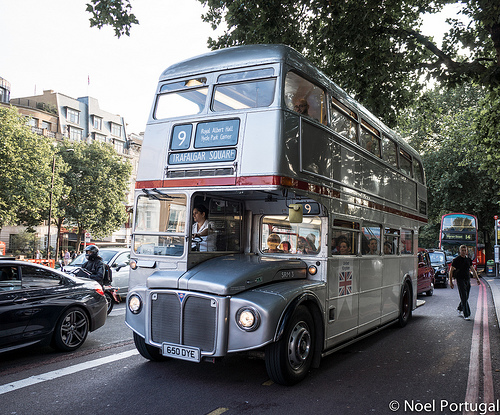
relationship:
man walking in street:
[447, 244, 481, 321] [408, 330, 468, 395]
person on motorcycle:
[75, 245, 105, 287] [58, 226, 116, 281]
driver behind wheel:
[192, 205, 217, 252] [183, 233, 200, 242]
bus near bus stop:
[436, 213, 478, 273] [476, 248, 486, 266]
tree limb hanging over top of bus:
[199, 2, 499, 85] [120, 37, 432, 388]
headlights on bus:
[127, 294, 257, 332] [135, 50, 465, 390]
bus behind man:
[439, 213, 495, 272] [447, 244, 481, 321]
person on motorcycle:
[73, 244, 115, 288] [56, 263, 118, 318]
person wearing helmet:
[73, 244, 115, 288] [82, 241, 100, 263]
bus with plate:
[120, 37, 432, 388] [155, 335, 207, 369]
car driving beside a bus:
[33, 264, 163, 394] [119, 87, 363, 385]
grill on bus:
[149, 298, 218, 353] [120, 37, 432, 388]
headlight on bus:
[235, 301, 261, 333] [120, 37, 432, 388]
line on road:
[6, 351, 133, 400] [0, 262, 494, 407]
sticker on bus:
[338, 262, 356, 312] [120, 37, 432, 388]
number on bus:
[172, 126, 192, 148] [120, 37, 432, 388]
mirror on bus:
[284, 188, 304, 224] [120, 37, 432, 388]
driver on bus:
[183, 203, 215, 248] [120, 37, 432, 388]